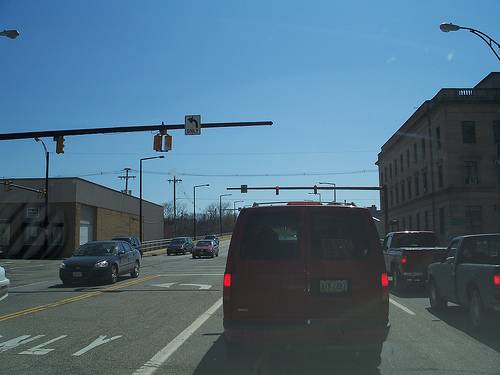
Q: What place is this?
A: It is a street.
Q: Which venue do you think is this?
A: This is a street.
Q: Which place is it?
A: It is a street.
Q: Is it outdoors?
A: Yes, it is outdoors.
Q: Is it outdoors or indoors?
A: It is outdoors.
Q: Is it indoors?
A: No, it is outdoors.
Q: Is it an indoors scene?
A: No, it is outdoors.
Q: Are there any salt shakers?
A: No, there are no salt shakers.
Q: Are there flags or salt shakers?
A: No, there are no salt shakers or flags.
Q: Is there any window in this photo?
A: Yes, there are windows.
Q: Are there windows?
A: Yes, there are windows.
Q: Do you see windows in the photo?
A: Yes, there are windows.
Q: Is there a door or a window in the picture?
A: Yes, there are windows.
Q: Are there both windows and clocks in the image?
A: No, there are windows but no clocks.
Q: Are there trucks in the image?
A: Yes, there is a truck.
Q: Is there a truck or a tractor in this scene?
A: Yes, there is a truck.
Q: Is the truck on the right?
A: Yes, the truck is on the right of the image.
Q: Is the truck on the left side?
A: No, the truck is on the right of the image.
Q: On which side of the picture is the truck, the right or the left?
A: The truck is on the right of the image.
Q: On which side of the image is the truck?
A: The truck is on the right of the image.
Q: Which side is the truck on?
A: The truck is on the right of the image.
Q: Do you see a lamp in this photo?
A: Yes, there is a lamp.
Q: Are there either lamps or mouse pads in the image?
A: Yes, there is a lamp.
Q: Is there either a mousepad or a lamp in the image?
A: Yes, there is a lamp.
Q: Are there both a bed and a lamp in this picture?
A: No, there is a lamp but no beds.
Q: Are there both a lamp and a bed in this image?
A: No, there is a lamp but no beds.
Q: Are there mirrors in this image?
A: No, there are no mirrors.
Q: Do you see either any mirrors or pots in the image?
A: No, there are no mirrors or pots.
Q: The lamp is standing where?
A: The lamp is standing on the sidewalk.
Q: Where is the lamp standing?
A: The lamp is standing on the sidewalk.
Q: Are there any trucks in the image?
A: Yes, there is a truck.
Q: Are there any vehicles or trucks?
A: Yes, there is a truck.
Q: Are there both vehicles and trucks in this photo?
A: Yes, there are both a truck and a vehicle.